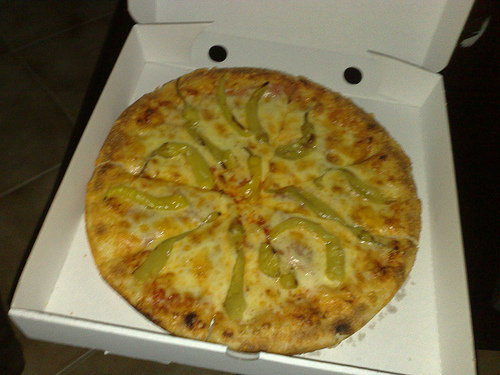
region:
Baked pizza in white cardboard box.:
[8, 2, 475, 373]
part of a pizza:
[265, 148, 302, 190]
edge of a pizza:
[344, 295, 378, 342]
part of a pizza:
[308, 262, 335, 293]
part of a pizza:
[383, 333, 407, 360]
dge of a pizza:
[374, 270, 397, 295]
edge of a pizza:
[451, 242, 466, 281]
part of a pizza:
[332, 250, 371, 288]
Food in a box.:
[4, 3, 486, 369]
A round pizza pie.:
[81, 59, 426, 360]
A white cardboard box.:
[6, 1, 485, 373]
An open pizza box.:
[5, 5, 492, 372]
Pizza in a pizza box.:
[7, 3, 487, 374]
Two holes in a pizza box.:
[186, 25, 375, 97]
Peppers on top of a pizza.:
[74, 63, 426, 363]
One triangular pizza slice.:
[241, 195, 421, 340]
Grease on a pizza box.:
[330, 265, 420, 365]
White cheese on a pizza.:
[174, 236, 232, 297]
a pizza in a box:
[42, 49, 479, 344]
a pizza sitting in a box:
[60, 75, 470, 337]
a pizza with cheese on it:
[73, 54, 453, 320]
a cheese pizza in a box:
[36, 40, 498, 359]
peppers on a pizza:
[91, 71, 470, 290]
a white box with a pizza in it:
[53, 45, 476, 352]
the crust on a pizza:
[94, 51, 434, 299]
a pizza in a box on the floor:
[29, 36, 487, 338]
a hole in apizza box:
[197, 28, 247, 65]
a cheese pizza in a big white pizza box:
[80, 75, 436, 345]